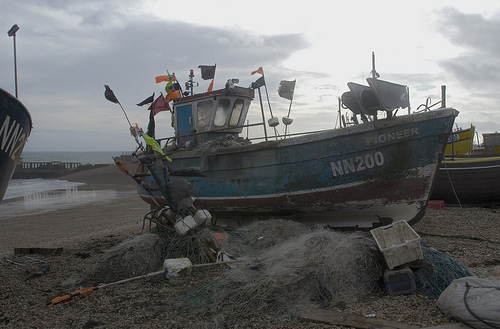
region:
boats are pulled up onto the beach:
[8, 45, 499, 297]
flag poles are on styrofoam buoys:
[53, 125, 228, 308]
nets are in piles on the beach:
[243, 224, 469, 306]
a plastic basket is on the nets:
[368, 215, 429, 272]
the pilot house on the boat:
[168, 85, 256, 160]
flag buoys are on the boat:
[108, 63, 431, 165]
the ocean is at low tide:
[15, 150, 152, 277]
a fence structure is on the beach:
[17, 146, 112, 188]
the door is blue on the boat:
[171, 93, 200, 158]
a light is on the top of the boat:
[177, 65, 202, 104]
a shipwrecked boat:
[101, 49, 459, 241]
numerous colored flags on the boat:
[91, 58, 301, 148]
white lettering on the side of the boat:
[325, 127, 422, 175]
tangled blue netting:
[410, 242, 470, 298]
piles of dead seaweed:
[96, 217, 384, 315]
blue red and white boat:
[139, 75, 459, 227]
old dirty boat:
[125, 83, 456, 229]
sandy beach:
[0, 165, 142, 234]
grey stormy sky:
[11, 9, 492, 149]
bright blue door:
[174, 102, 195, 147]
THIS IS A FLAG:
[96, 81, 126, 106]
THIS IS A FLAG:
[147, 91, 167, 128]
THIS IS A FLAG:
[138, 87, 153, 111]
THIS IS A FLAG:
[155, 70, 180, 87]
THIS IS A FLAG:
[197, 65, 221, 78]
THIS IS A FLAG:
[249, 65, 266, 77]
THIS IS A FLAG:
[278, 74, 303, 118]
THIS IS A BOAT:
[124, 91, 449, 235]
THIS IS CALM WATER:
[21, 165, 49, 199]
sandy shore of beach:
[10, 185, 202, 324]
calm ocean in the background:
[15, 135, 135, 162]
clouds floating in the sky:
[25, 14, 165, 82]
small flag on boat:
[278, 72, 293, 101]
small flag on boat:
[255, 75, 265, 92]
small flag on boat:
[256, 64, 268, 78]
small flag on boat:
[197, 55, 221, 83]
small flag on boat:
[142, 72, 178, 82]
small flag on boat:
[93, 85, 124, 105]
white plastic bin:
[367, 220, 424, 266]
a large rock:
[164, 256, 196, 279]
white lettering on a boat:
[326, 150, 383, 176]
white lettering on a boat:
[365, 128, 419, 145]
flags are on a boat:
[143, 59, 298, 145]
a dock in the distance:
[13, 159, 103, 181]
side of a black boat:
[0, 88, 31, 234]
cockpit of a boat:
[172, 91, 252, 144]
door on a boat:
[177, 101, 194, 146]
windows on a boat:
[195, 98, 243, 128]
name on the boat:
[351, 121, 437, 151]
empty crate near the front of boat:
[367, 216, 428, 271]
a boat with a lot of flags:
[90, 45, 461, 235]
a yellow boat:
[435, 121, 480, 163]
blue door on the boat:
[173, 102, 199, 148]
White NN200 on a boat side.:
[328, 151, 386, 178]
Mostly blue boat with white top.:
[112, 84, 459, 231]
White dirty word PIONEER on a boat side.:
[363, 125, 420, 146]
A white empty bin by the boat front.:
[368, 218, 425, 270]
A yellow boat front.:
[446, 123, 476, 156]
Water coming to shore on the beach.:
[1, 177, 116, 212]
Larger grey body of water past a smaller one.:
[18, 148, 140, 162]